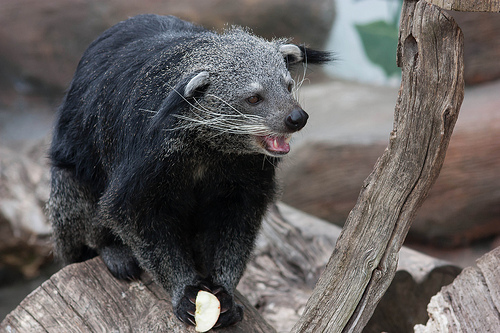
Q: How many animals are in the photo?
A: One.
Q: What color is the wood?
A: Brown.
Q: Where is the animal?
A: On a log.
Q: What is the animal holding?
A: Food.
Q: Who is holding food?
A: The animal.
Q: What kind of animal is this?
A: Wolverine.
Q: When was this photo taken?
A: During the day.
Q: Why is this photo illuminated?
A: Sunlight.